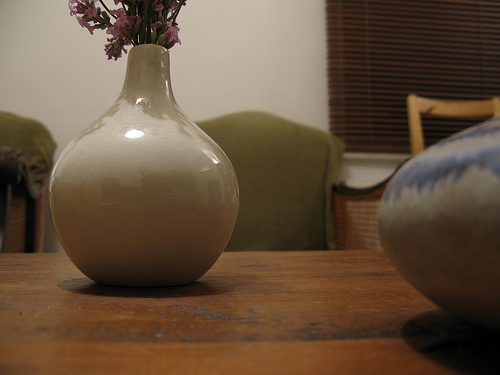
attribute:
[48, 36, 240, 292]
vase — white, round, shiny, tan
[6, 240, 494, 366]
table — wooden, brown, stained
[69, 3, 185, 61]
flowers — pink, purple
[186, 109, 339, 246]
chair — green, brown, empty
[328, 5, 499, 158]
blinds — brown, down